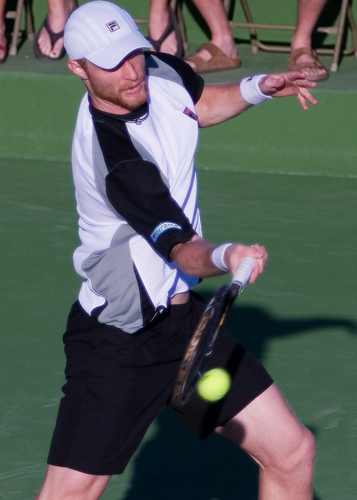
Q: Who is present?
A: A man.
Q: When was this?
A: Daytime.